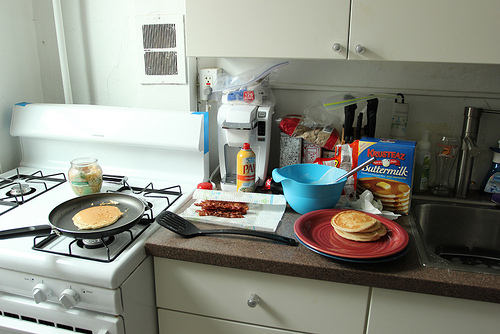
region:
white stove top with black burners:
[5, 98, 212, 332]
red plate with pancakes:
[296, 207, 409, 254]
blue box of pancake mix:
[355, 138, 415, 210]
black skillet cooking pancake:
[15, 187, 150, 253]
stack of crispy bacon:
[190, 195, 252, 221]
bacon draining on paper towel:
[192, 196, 255, 226]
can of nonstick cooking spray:
[235, 137, 264, 189]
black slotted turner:
[155, 205, 300, 252]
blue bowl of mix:
[267, 152, 350, 214]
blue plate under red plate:
[294, 206, 421, 269]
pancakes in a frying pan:
[15, 180, 138, 252]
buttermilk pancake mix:
[272, 130, 417, 210]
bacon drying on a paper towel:
[181, 183, 280, 232]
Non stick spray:
[229, 131, 262, 193]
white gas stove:
[2, 98, 134, 332]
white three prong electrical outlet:
[197, 61, 219, 107]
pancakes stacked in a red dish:
[289, 197, 404, 259]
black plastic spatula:
[153, 206, 301, 253]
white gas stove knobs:
[22, 275, 92, 321]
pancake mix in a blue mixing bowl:
[267, 138, 411, 208]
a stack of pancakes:
[328, 207, 393, 250]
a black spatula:
[148, 203, 298, 254]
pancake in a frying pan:
[2, 187, 154, 245]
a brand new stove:
[0, 96, 210, 331]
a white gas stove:
[3, 90, 208, 332]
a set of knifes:
[339, 90, 384, 151]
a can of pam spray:
[235, 140, 262, 192]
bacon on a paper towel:
[186, 191, 261, 222]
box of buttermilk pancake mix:
[347, 133, 419, 226]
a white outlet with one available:
[196, 66, 216, 102]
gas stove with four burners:
[0, 96, 211, 332]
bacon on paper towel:
[192, 197, 251, 219]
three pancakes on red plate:
[289, 203, 409, 260]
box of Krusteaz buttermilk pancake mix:
[353, 133, 413, 213]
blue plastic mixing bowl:
[271, 159, 350, 213]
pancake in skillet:
[3, 190, 150, 245]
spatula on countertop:
[155, 207, 302, 254]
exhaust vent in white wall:
[131, 11, 188, 87]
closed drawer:
[150, 254, 368, 332]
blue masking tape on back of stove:
[189, 105, 214, 154]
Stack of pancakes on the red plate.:
[331, 210, 390, 248]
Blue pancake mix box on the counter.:
[358, 140, 415, 216]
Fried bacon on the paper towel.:
[198, 191, 249, 218]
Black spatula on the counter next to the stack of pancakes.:
[159, 206, 301, 253]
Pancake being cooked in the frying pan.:
[67, 204, 127, 229]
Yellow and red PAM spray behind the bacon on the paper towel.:
[232, 137, 265, 194]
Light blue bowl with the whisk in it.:
[277, 151, 351, 202]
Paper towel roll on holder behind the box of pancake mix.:
[391, 89, 413, 139]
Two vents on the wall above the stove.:
[144, 19, 185, 84]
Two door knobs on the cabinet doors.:
[327, 36, 371, 59]